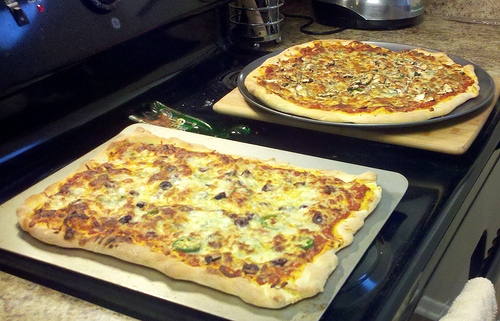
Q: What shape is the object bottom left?
A: Rectangle.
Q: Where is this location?
A: Kitchen.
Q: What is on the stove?
A: Pizza.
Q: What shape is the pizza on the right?
A: Circle.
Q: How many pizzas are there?
A: 2.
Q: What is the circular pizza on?
A: Cutting board.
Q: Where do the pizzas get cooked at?
A: Oven.